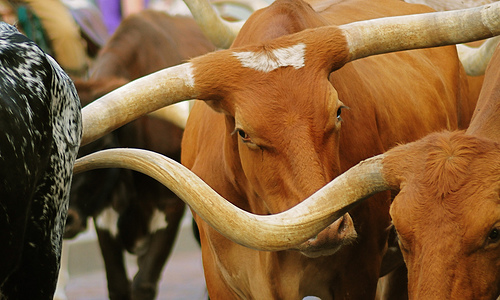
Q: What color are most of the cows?
A: Brown.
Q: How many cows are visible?
A: Four.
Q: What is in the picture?
A: Cows.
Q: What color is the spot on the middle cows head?
A: White.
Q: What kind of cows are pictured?
A: Longhorn.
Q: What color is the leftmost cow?
A: Black and white.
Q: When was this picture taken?
A: Daytime.